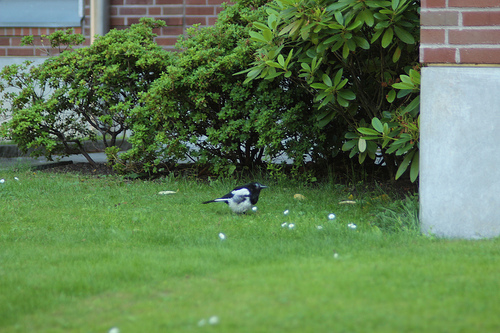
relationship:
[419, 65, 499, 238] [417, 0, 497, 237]
base of building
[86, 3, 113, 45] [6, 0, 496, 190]
pipe attached to building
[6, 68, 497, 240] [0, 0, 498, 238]
cement foundation on building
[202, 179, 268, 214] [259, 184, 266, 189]
bird has beak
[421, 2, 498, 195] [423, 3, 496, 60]
wall has bricks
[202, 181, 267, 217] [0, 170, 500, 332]
bird in grass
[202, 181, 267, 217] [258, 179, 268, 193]
bird has beak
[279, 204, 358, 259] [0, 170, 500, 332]
weeds in grass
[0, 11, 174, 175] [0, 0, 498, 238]
bush near building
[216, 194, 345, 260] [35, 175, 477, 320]
white flowers in grass